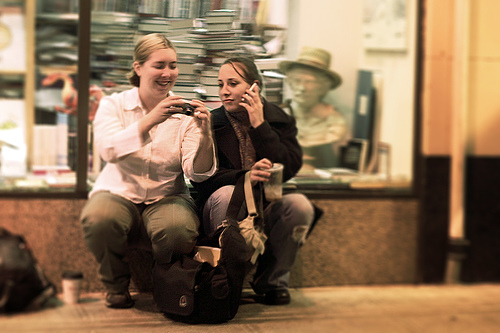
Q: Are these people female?
A: Yes, all the people are female.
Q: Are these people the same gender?
A: Yes, all the people are female.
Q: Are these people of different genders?
A: No, all the people are female.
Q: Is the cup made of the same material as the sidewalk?
A: No, the cup is made of plastic and the sidewalk is made of concrete.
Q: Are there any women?
A: Yes, there is a woman.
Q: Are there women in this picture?
A: Yes, there is a woman.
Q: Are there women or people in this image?
A: Yes, there is a woman.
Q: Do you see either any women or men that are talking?
A: Yes, the woman is talking.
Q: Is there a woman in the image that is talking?
A: Yes, there is a woman that is talking.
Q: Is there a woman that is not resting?
A: Yes, there is a woman that is talking.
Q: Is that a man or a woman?
A: That is a woman.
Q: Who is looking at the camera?
A: The woman is looking at the camera.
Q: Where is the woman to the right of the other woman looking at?
A: The woman is looking at the camera.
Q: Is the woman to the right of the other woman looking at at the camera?
A: Yes, the woman is looking at the camera.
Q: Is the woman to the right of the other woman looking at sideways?
A: No, the woman is looking at the camera.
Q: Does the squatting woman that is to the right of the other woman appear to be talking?
A: Yes, the woman is talking.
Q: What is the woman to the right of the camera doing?
A: The woman is talking.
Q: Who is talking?
A: The woman is talking.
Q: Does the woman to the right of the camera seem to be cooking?
A: No, the woman is talking.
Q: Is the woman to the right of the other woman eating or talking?
A: The woman is talking.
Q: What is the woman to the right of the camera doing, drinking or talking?
A: The woman is talking.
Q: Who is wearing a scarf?
A: The woman is wearing a scarf.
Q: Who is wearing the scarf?
A: The woman is wearing a scarf.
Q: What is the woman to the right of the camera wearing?
A: The woman is wearing a scarf.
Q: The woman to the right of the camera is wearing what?
A: The woman is wearing a scarf.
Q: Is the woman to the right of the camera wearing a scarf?
A: Yes, the woman is wearing a scarf.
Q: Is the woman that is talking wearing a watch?
A: No, the woman is wearing a scarf.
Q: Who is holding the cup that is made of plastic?
A: The woman is holding the cup.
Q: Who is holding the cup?
A: The woman is holding the cup.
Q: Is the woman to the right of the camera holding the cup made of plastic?
A: Yes, the woman is holding the cup.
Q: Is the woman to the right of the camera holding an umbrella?
A: No, the woman is holding the cup.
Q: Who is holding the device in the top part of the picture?
A: The woman is holding the cell phone.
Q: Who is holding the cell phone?
A: The woman is holding the cell phone.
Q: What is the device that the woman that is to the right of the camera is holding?
A: The device is a cell phone.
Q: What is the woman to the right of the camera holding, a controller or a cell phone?
A: The woman is holding a cell phone.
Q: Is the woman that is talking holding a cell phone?
A: Yes, the woman is holding a cell phone.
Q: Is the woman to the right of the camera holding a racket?
A: No, the woman is holding a cell phone.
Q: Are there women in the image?
A: Yes, there is a woman.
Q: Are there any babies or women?
A: Yes, there is a woman.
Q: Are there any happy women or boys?
A: Yes, there is a happy woman.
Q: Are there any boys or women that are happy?
A: Yes, the woman is happy.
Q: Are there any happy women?
A: Yes, there is a happy woman.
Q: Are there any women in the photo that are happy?
A: Yes, there is a woman that is happy.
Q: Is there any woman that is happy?
A: Yes, there is a woman that is happy.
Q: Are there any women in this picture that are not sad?
A: Yes, there is a happy woman.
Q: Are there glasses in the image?
A: No, there are no glasses.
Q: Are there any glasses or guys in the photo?
A: No, there are no glasses or guys.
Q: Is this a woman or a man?
A: This is a woman.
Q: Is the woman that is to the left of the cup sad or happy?
A: The woman is happy.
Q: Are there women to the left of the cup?
A: Yes, there is a woman to the left of the cup.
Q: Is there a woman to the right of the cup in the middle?
A: No, the woman is to the left of the cup.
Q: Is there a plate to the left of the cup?
A: No, there is a woman to the left of the cup.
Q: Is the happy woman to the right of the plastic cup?
A: No, the woman is to the left of the cup.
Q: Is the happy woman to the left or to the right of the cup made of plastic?
A: The woman is to the left of the cup.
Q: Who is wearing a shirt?
A: The woman is wearing a shirt.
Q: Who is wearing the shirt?
A: The woman is wearing a shirt.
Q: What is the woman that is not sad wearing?
A: The woman is wearing a shirt.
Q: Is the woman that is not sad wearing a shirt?
A: Yes, the woman is wearing a shirt.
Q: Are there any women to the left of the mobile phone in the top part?
A: Yes, there is a woman to the left of the cellphone.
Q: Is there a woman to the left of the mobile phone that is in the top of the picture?
A: Yes, there is a woman to the left of the cellphone.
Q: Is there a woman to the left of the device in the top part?
A: Yes, there is a woman to the left of the cellphone.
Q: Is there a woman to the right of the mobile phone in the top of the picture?
A: No, the woman is to the left of the cell phone.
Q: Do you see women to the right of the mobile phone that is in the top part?
A: No, the woman is to the left of the cell phone.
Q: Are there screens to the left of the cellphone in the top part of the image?
A: No, there is a woman to the left of the cellphone.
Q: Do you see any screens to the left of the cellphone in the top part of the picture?
A: No, there is a woman to the left of the cellphone.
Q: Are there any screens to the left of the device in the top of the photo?
A: No, there is a woman to the left of the cellphone.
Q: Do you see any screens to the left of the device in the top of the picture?
A: No, there is a woman to the left of the cellphone.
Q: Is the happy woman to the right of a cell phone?
A: No, the woman is to the left of a cell phone.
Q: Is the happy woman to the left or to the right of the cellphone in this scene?
A: The woman is to the left of the cellphone.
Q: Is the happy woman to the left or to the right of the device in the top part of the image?
A: The woman is to the left of the cellphone.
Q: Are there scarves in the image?
A: Yes, there is a scarf.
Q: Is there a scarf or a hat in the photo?
A: Yes, there is a scarf.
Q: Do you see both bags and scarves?
A: Yes, there are both a scarf and a bag.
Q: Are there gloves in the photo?
A: No, there are no gloves.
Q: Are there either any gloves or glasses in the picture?
A: No, there are no gloves or glasses.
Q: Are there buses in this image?
A: No, there are no buses.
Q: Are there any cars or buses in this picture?
A: No, there are no buses or cars.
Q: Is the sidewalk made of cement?
A: Yes, the sidewalk is made of cement.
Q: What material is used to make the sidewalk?
A: The sidewalk is made of concrete.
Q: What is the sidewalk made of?
A: The sidewalk is made of concrete.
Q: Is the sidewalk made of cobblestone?
A: No, the sidewalk is made of concrete.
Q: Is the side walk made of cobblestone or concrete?
A: The side walk is made of concrete.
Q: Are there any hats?
A: Yes, there is a hat.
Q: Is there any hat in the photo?
A: Yes, there is a hat.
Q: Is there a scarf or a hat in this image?
A: Yes, there is a hat.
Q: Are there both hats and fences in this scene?
A: No, there is a hat but no fences.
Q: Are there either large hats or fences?
A: Yes, there is a large hat.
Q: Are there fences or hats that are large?
A: Yes, the hat is large.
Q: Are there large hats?
A: Yes, there is a large hat.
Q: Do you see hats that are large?
A: Yes, there is a hat that is large.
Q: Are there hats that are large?
A: Yes, there is a hat that is large.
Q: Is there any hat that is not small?
A: Yes, there is a large hat.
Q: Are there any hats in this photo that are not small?
A: Yes, there is a large hat.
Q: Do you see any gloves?
A: No, there are no gloves.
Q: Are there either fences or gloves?
A: No, there are no gloves or fences.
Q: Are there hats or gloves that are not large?
A: No, there is a hat but it is large.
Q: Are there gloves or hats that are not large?
A: No, there is a hat but it is large.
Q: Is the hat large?
A: Yes, the hat is large.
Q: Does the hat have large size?
A: Yes, the hat is large.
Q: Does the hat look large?
A: Yes, the hat is large.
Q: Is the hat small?
A: No, the hat is large.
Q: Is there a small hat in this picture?
A: No, there is a hat but it is large.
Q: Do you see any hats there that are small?
A: No, there is a hat but it is large.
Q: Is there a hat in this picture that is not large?
A: No, there is a hat but it is large.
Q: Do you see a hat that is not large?
A: No, there is a hat but it is large.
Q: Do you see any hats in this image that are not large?
A: No, there is a hat but it is large.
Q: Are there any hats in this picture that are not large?
A: No, there is a hat but it is large.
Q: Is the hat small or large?
A: The hat is large.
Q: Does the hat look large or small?
A: The hat is large.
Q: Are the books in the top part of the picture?
A: Yes, the books are in the top of the image.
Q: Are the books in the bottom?
A: No, the books are in the top of the image.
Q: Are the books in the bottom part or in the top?
A: The books are in the top of the image.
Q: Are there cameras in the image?
A: Yes, there is a camera.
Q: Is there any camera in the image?
A: Yes, there is a camera.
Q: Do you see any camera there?
A: Yes, there is a camera.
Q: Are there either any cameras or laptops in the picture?
A: Yes, there is a camera.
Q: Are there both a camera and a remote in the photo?
A: No, there is a camera but no remote controls.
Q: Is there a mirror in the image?
A: No, there are no mirrors.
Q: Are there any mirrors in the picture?
A: No, there are no mirrors.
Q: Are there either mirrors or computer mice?
A: No, there are no mirrors or computer mice.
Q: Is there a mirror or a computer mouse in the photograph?
A: No, there are no mirrors or computer mice.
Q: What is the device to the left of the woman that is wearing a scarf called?
A: The device is a camera.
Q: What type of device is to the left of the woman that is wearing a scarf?
A: The device is a camera.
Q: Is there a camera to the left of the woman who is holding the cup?
A: Yes, there is a camera to the left of the woman.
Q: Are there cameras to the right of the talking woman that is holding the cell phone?
A: No, the camera is to the left of the woman.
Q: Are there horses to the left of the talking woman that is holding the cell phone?
A: No, there is a camera to the left of the woman.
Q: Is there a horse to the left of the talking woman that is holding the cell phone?
A: No, there is a camera to the left of the woman.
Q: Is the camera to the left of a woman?
A: Yes, the camera is to the left of a woman.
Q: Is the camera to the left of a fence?
A: No, the camera is to the left of a woman.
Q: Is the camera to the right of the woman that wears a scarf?
A: No, the camera is to the left of the woman.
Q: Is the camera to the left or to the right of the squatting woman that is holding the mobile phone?
A: The camera is to the left of the woman.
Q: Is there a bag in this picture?
A: Yes, there is a bag.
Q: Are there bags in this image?
A: Yes, there is a bag.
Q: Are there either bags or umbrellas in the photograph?
A: Yes, there is a bag.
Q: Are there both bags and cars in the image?
A: No, there is a bag but no cars.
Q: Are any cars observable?
A: No, there are no cars.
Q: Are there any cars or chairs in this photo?
A: No, there are no cars or chairs.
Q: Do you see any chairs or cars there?
A: No, there are no cars or chairs.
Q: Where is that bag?
A: The bag is on the sidewalk.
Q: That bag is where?
A: The bag is on the sidewalk.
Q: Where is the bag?
A: The bag is on the sidewalk.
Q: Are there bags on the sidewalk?
A: Yes, there is a bag on the sidewalk.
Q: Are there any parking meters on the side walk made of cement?
A: No, there is a bag on the side walk.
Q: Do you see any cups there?
A: Yes, there is a cup.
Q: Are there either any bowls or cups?
A: Yes, there is a cup.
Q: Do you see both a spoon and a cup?
A: No, there is a cup but no spoons.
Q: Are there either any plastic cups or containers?
A: Yes, there is a plastic cup.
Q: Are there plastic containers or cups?
A: Yes, there is a plastic cup.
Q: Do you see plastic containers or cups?
A: Yes, there is a plastic cup.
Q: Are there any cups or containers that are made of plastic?
A: Yes, the cup is made of plastic.